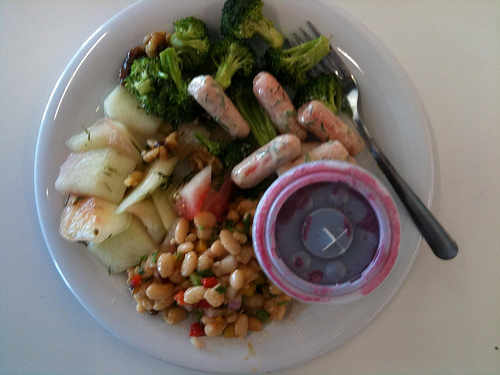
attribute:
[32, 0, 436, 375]
plate — white, circular, shiny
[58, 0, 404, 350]
meal — vegetarian, healthy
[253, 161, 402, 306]
container — small, plastic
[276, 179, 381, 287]
sauce — red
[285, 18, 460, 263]
fork — silver, stainless steel, shiny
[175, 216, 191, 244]
bean — small, white, tan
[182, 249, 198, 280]
bean — white, small, tan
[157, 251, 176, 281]
bean — tan, white, small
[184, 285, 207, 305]
bean — tan, white, small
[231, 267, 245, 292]
bean — white, small, tan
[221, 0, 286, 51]
broccoli — steamed, green, fresh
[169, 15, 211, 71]
broccoli — steamed, green, fresh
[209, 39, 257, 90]
broccoli — steamed, green, fresh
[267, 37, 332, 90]
broccoli — steamed, green, fresh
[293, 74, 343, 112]
broccoli — steamed, green, fresh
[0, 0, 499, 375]
surface — white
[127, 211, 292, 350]
beans — caviar, cold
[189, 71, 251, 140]
sausage — tofu, unsmoked, spicy, mini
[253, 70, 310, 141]
sausage — tofu, unsmoked, spicy, mini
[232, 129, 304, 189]
sausage — tofu, unsmoked, spicy, mini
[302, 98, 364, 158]
sausage — tofu, unsmoked, spicy, mini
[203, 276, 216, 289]
pepper — red, fresh, ripe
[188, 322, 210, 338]
tomato — ripe, red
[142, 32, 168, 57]
candy — shelled, coated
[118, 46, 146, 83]
walnut — brown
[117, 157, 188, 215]
carrot — white